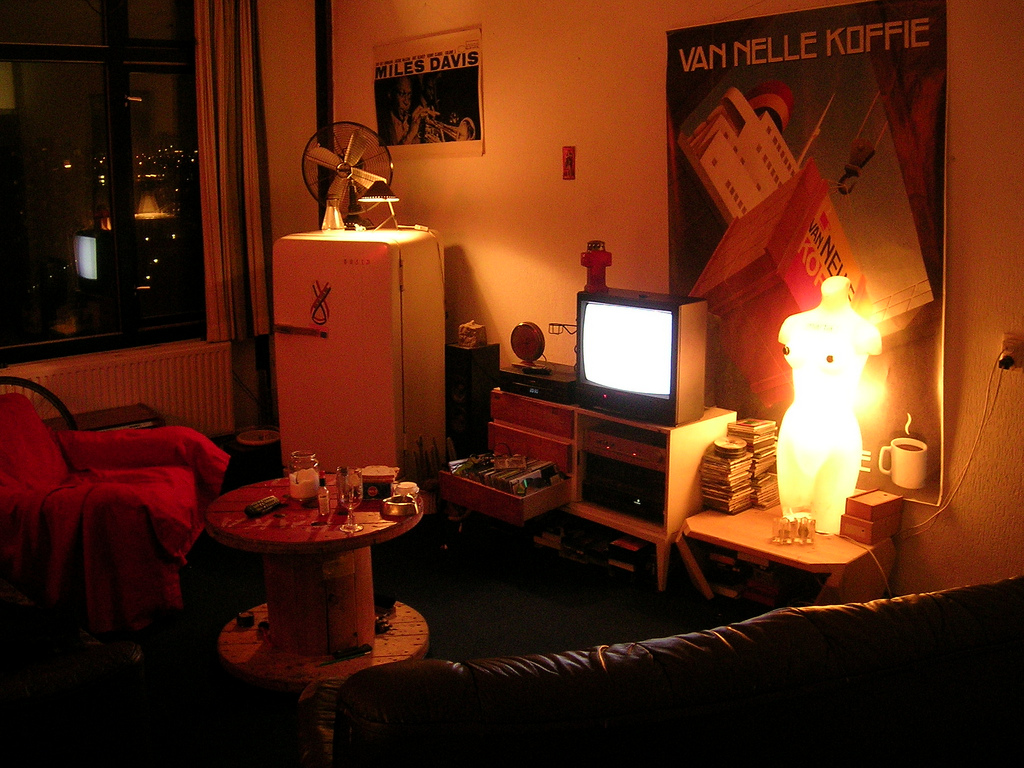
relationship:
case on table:
[335, 504, 383, 539] [196, 458, 428, 677]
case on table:
[700, 448, 755, 464] [680, 493, 879, 614]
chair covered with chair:
[6, 383, 251, 639] [0, 383, 228, 635]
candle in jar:
[293, 469, 324, 502] [280, 444, 317, 503]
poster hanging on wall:
[360, 27, 495, 151] [326, 13, 992, 487]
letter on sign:
[710, 37, 732, 70] [648, 24, 962, 485]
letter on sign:
[827, 24, 836, 59] [669, 26, 948, 511]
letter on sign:
[676, 42, 698, 73] [648, 24, 962, 485]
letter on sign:
[773, 26, 808, 70] [669, 26, 948, 511]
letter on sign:
[881, 14, 897, 53] [650, 1, 962, 513]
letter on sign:
[846, 22, 868, 55] [672, 39, 958, 539]